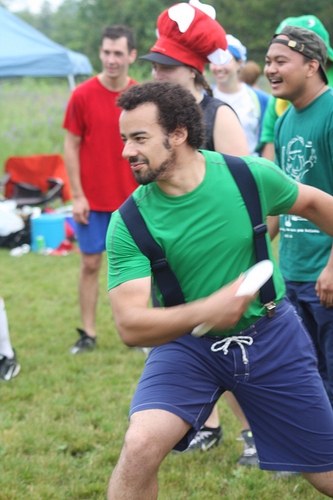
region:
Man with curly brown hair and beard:
[113, 80, 205, 185]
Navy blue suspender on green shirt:
[111, 197, 191, 302]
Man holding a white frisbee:
[182, 260, 281, 337]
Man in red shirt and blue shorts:
[59, 23, 140, 272]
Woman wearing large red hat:
[139, 3, 229, 98]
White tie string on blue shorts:
[177, 332, 308, 404]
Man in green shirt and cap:
[260, 25, 331, 169]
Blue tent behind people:
[0, 3, 97, 101]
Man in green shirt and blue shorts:
[96, 82, 331, 473]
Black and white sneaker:
[181, 422, 223, 453]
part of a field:
[238, 480, 242, 483]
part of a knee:
[135, 448, 149, 465]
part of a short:
[261, 445, 262, 449]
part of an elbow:
[131, 325, 137, 339]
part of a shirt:
[195, 285, 200, 289]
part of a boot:
[210, 432, 221, 444]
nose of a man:
[125, 150, 141, 155]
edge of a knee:
[132, 443, 140, 447]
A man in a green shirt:
[104, 80, 330, 496]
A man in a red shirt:
[62, 24, 140, 356]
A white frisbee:
[190, 255, 268, 334]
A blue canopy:
[0, 4, 93, 88]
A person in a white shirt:
[202, 33, 273, 160]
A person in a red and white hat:
[135, 0, 249, 160]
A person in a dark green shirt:
[264, 23, 332, 405]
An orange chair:
[2, 156, 72, 202]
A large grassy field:
[0, 91, 331, 498]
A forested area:
[3, 1, 331, 75]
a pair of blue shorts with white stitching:
[128, 306, 331, 471]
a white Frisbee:
[194, 257, 271, 332]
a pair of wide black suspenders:
[117, 154, 275, 312]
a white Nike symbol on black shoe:
[182, 427, 221, 450]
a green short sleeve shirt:
[105, 149, 297, 328]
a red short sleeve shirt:
[64, 77, 142, 213]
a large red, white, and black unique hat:
[145, 1, 229, 71]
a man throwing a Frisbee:
[106, 86, 332, 496]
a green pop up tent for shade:
[0, 2, 90, 88]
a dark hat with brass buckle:
[271, 26, 327, 86]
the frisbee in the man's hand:
[192, 258, 272, 341]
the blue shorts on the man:
[127, 296, 331, 472]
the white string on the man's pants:
[211, 335, 252, 363]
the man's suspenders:
[117, 150, 275, 321]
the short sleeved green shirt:
[104, 149, 298, 336]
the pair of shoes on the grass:
[172, 423, 260, 468]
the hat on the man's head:
[265, 25, 328, 84]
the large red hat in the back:
[149, 1, 227, 73]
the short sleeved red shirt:
[61, 74, 140, 211]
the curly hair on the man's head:
[115, 80, 205, 148]